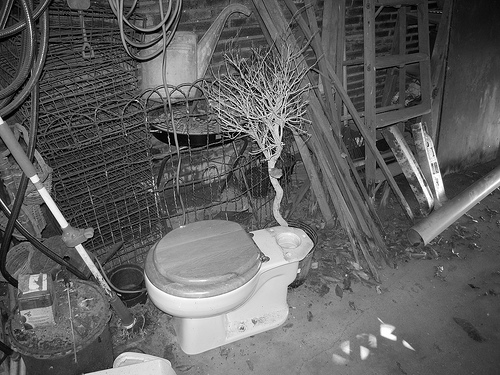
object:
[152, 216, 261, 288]
lid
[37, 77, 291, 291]
fencing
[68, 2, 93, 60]
shovel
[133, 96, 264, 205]
grill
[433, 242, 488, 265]
leaves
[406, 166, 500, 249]
pipe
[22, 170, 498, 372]
ground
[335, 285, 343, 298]
leaf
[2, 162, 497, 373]
floor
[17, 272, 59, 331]
box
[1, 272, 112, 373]
bucket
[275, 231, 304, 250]
pot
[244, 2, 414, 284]
posts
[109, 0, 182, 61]
cord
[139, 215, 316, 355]
toilet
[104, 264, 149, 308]
bucket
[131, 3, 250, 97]
can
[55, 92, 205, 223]
fence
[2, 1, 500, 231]
brick wall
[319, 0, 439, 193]
ladder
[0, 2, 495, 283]
wall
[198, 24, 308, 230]
leafless tree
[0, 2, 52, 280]
hose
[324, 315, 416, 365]
sunlight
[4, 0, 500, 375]
alley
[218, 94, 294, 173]
grass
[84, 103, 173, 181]
loops